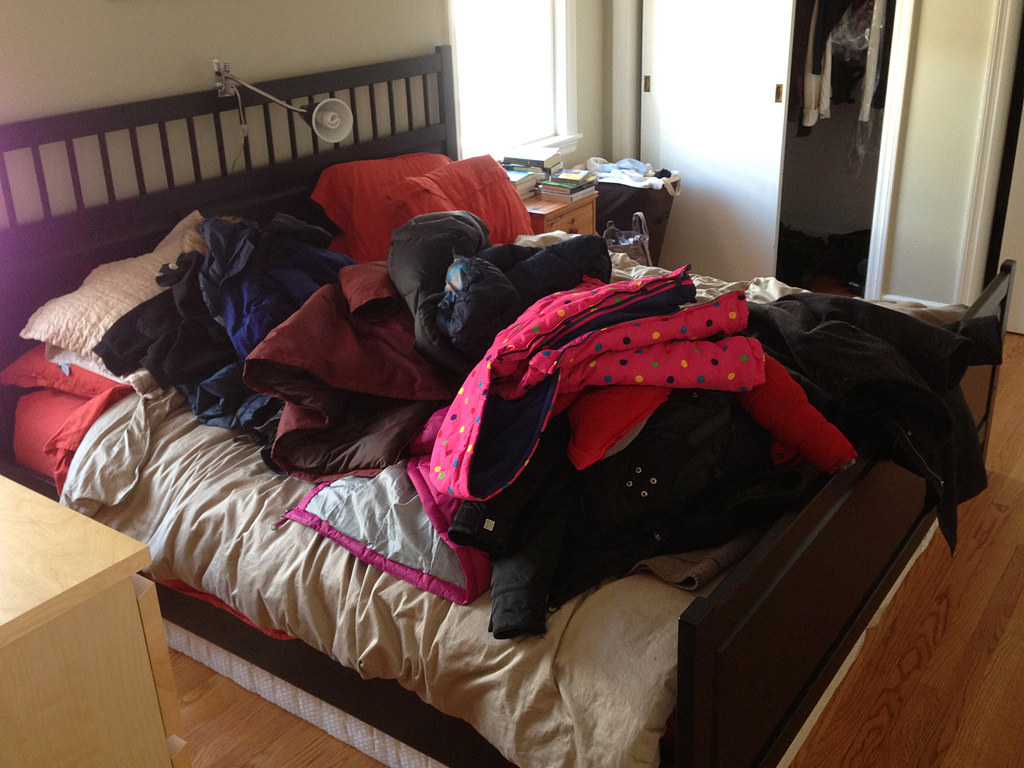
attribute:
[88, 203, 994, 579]
jackets — jumbled, piled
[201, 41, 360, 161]
lamp — clipped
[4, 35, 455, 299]
headboard — dark, brown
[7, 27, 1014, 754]
bed — full sized, wooden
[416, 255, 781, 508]
coat — colorful, pik, pink, polka dotted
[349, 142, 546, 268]
pillow — red, orange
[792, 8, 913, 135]
clothes — hanging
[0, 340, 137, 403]
pillow — red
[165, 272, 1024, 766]
floor — hardwood, wooden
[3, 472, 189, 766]
dresser — wood, wooden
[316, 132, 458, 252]
pillow — red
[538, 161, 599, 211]
books — piled, stacked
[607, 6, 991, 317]
closet — ope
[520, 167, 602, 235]
dresser — wood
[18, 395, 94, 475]
sheets — red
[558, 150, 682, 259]
laundry hamper — full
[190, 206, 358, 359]
coat — blue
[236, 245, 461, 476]
jacket — maroon